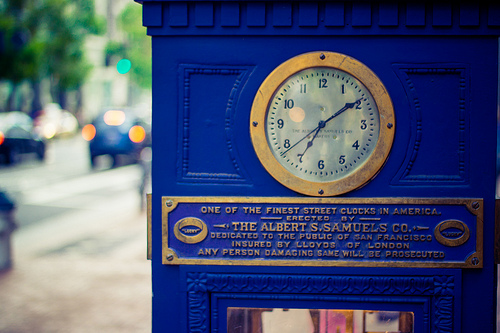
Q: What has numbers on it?
A: The clock.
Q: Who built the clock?
A: The Albert S. Samuels Co.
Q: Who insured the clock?
A: Lloyd's of London.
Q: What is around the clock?
A: Gold trim.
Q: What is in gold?
A: The letters.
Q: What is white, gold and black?
A: A street clock.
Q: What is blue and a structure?
A: A street clock.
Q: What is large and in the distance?
A: A tree.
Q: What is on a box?
A: A clock.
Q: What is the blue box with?
A: A clock.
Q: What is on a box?
A: A plaque.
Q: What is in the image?
A: Plaque with words.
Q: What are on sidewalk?
A: Blurry trees.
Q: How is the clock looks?
A: Gold trim.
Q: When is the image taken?
A: 7.10.